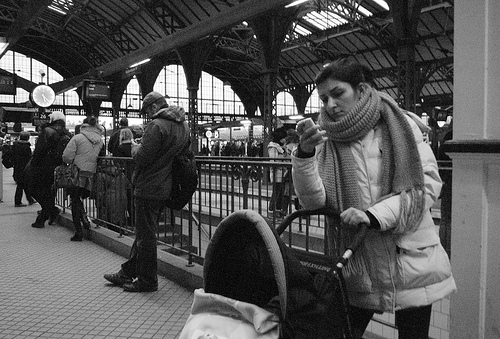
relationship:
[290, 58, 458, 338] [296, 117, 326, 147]
person looking at cell phone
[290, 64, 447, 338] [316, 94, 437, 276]
person wearing scarf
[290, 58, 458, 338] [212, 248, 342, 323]
person holding onto stroller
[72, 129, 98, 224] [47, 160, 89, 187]
person holding bag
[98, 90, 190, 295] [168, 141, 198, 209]
man holding back pack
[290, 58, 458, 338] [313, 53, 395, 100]
person has hair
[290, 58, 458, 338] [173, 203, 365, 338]
person with stroller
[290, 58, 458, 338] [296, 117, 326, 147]
person holding cell phone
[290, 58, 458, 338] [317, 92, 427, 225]
person wearing scarf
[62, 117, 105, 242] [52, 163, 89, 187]
person holding bag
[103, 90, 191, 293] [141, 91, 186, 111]
man wearing hat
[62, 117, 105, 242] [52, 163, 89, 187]
person with bag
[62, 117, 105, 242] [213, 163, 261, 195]
person leaning on railing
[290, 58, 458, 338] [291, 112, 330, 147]
person holding cell phone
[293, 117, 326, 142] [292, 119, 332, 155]
cell phone in hand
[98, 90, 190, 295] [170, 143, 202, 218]
man wearing backpack